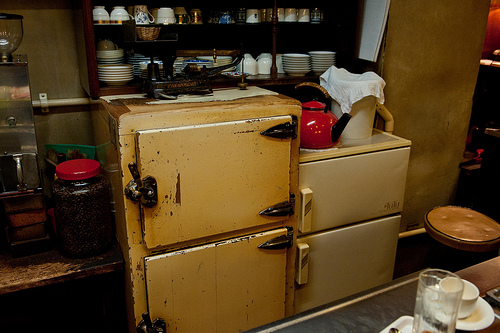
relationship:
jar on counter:
[44, 153, 124, 261] [3, 238, 137, 298]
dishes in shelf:
[87, 41, 133, 93] [72, 0, 380, 93]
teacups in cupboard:
[88, 9, 331, 24] [83, 6, 363, 40]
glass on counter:
[405, 252, 472, 330] [264, 261, 455, 332]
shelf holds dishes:
[72, 0, 380, 93] [87, 41, 133, 93]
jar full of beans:
[44, 153, 124, 261] [58, 181, 105, 243]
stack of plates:
[99, 51, 137, 89] [279, 46, 323, 80]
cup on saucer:
[435, 278, 484, 315] [413, 267, 496, 331]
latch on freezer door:
[290, 181, 317, 241] [297, 143, 414, 226]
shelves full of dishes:
[72, 0, 380, 93] [87, 41, 133, 93]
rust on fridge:
[164, 170, 193, 206] [104, 93, 307, 332]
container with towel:
[319, 81, 381, 148] [322, 61, 393, 108]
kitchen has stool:
[17, 20, 497, 318] [421, 192, 499, 251]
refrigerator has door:
[104, 93, 307, 332] [116, 118, 303, 237]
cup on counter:
[435, 278, 484, 315] [264, 261, 455, 332]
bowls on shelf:
[243, 46, 285, 73] [72, 0, 380, 93]